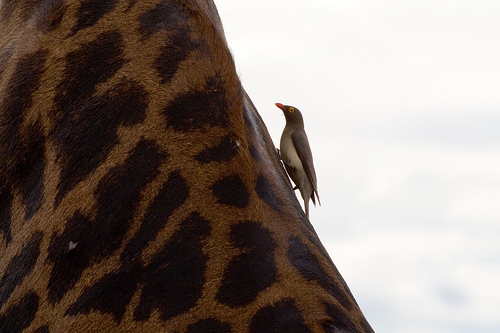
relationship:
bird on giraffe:
[273, 102, 322, 221] [51, 0, 300, 325]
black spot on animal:
[192, 135, 242, 165] [0, 5, 260, 329]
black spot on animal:
[162, 69, 235, 131] [2, 2, 380, 331]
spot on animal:
[280, 228, 352, 310] [2, 2, 380, 331]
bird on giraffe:
[273, 102, 322, 221] [5, 3, 267, 331]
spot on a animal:
[212, 216, 280, 312] [0, 0, 372, 333]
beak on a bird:
[274, 96, 305, 113] [284, 90, 342, 180]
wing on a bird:
[288, 136, 331, 188] [242, 70, 337, 214]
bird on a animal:
[273, 102, 322, 221] [0, 0, 372, 333]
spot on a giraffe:
[285, 233, 355, 313] [10, 10, 362, 308]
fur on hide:
[70, 68, 159, 168] [5, 2, 376, 331]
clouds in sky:
[214, 0, 499, 332] [214, 0, 498, 332]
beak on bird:
[275, 102, 286, 111] [261, 88, 336, 216]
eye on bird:
[289, 107, 295, 113] [262, 89, 329, 208]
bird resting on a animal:
[273, 102, 322, 221] [0, 0, 372, 333]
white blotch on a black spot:
[359, 68, 434, 216] [38, 134, 210, 324]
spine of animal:
[184, 5, 373, 331] [0, 0, 372, 333]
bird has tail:
[273, 102, 322, 221] [301, 194, 317, 224]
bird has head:
[273, 102, 322, 221] [273, 100, 307, 123]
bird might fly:
[247, 64, 374, 234] [67, 228, 84, 268]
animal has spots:
[0, 0, 372, 333] [20, 5, 207, 313]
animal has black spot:
[0, 0, 372, 333] [158, 70, 234, 134]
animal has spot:
[0, 0, 372, 333] [198, 196, 296, 307]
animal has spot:
[0, 0, 372, 333] [14, 46, 170, 166]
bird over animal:
[273, 102, 322, 221] [0, 0, 372, 333]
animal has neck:
[0, 0, 372, 333] [8, 14, 244, 255]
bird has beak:
[273, 102, 322, 221] [271, 95, 291, 115]